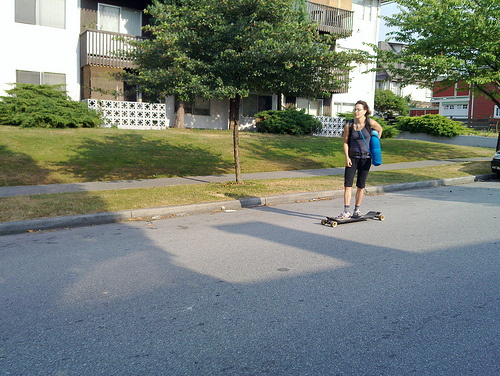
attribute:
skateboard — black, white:
[318, 209, 389, 229]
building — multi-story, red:
[406, 74, 498, 130]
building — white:
[2, 1, 385, 145]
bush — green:
[1, 83, 106, 136]